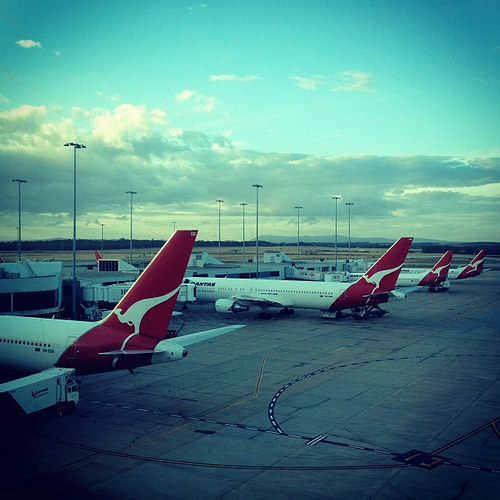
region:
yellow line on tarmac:
[197, 386, 273, 413]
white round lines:
[249, 382, 296, 423]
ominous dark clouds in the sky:
[159, 150, 314, 200]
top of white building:
[7, 251, 71, 286]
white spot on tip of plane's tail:
[184, 224, 214, 244]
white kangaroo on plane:
[101, 289, 194, 358]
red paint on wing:
[75, 220, 208, 382]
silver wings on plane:
[221, 290, 286, 320]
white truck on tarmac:
[21, 360, 88, 424]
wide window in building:
[21, 282, 68, 316]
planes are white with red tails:
[1, 226, 493, 379]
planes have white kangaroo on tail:
[105, 228, 485, 373]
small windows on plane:
[2, 229, 454, 356]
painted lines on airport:
[80, 301, 498, 487]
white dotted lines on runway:
[76, 348, 498, 476]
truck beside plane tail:
[1, 365, 79, 420]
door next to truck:
[61, 333, 81, 360]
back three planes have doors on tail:
[336, 268, 470, 303]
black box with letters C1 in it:
[392, 445, 452, 471]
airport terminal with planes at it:
[1, 249, 374, 316]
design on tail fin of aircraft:
[100, 283, 202, 361]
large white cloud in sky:
[92, 114, 221, 186]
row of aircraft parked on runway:
[22, 199, 479, 372]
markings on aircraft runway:
[372, 435, 479, 483]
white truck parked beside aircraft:
[0, 357, 92, 436]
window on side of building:
[0, 290, 66, 320]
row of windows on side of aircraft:
[0, 325, 61, 348]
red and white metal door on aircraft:
[56, 332, 92, 366]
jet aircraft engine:
[203, 289, 246, 321]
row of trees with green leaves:
[26, 230, 76, 250]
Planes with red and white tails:
[45, 210, 496, 394]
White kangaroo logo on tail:
[105, 282, 186, 369]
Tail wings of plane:
[90, 317, 252, 372]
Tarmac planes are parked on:
[7, 282, 497, 494]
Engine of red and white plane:
[204, 290, 251, 322]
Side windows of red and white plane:
[0, 334, 57, 359]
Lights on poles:
[8, 135, 368, 246]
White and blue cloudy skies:
[2, 5, 495, 242]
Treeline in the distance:
[10, 226, 490, 262]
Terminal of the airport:
[2, 256, 376, 317]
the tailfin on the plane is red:
[87, 223, 189, 368]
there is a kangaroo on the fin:
[94, 216, 196, 368]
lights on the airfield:
[56, 136, 93, 310]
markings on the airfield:
[241, 343, 498, 455]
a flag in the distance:
[91, 249, 105, 264]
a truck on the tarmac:
[1, 364, 91, 415]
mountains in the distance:
[7, 237, 284, 253]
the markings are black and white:
[236, 335, 491, 472]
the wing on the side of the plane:
[224, 290, 299, 326]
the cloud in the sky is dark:
[239, 153, 498, 225]